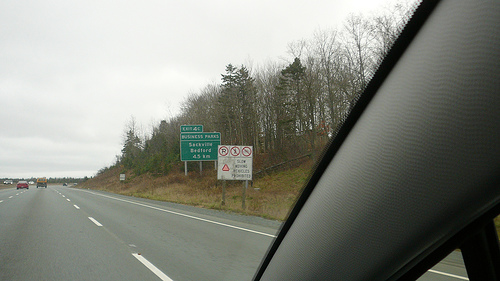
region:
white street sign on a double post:
[214, 144, 254, 180]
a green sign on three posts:
[180, 123, 219, 161]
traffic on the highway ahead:
[0, 174, 52, 196]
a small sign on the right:
[117, 171, 125, 192]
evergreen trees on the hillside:
[214, 64, 254, 146]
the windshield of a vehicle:
[0, 0, 430, 276]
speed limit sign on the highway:
[118, 168, 127, 191]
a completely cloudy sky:
[0, 0, 424, 179]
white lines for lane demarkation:
[50, 183, 170, 279]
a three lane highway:
[0, 178, 252, 279]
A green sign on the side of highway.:
[156, 107, 228, 169]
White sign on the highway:
[198, 133, 255, 183]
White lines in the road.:
[56, 183, 131, 263]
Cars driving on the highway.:
[13, 177, 54, 206]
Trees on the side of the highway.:
[121, 111, 336, 150]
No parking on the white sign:
[214, 143, 231, 158]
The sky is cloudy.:
[37, 25, 207, 92]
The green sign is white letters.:
[188, 134, 215, 157]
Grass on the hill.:
[141, 164, 221, 201]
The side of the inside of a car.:
[355, 65, 469, 211]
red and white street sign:
[209, 141, 270, 183]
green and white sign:
[170, 114, 216, 166]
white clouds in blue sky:
[32, 37, 72, 80]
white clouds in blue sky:
[109, 36, 149, 62]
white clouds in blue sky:
[12, 51, 48, 93]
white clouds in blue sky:
[197, 30, 230, 60]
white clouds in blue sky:
[34, 83, 67, 114]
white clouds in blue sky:
[78, 24, 111, 59]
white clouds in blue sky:
[46, 91, 83, 136]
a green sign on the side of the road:
[179, 125, 219, 162]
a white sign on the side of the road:
[216, 145, 251, 180]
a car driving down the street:
[16, 180, 27, 189]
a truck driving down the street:
[36, 177, 47, 185]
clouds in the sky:
[3, 4, 107, 155]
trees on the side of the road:
[282, 20, 336, 152]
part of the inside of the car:
[291, 3, 493, 269]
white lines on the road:
[53, 183, 172, 278]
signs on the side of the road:
[180, 125, 254, 210]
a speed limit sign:
[120, 173, 125, 178]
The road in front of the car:
[3, 183, 470, 280]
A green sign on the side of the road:
[181, 125, 216, 175]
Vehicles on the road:
[18, 177, 47, 191]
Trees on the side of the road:
[108, 3, 415, 174]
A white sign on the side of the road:
[219, 143, 249, 203]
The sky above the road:
[1, 0, 414, 179]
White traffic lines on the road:
[52, 185, 164, 279]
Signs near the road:
[181, 125, 254, 202]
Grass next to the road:
[81, 163, 313, 219]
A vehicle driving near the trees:
[15, 177, 30, 189]